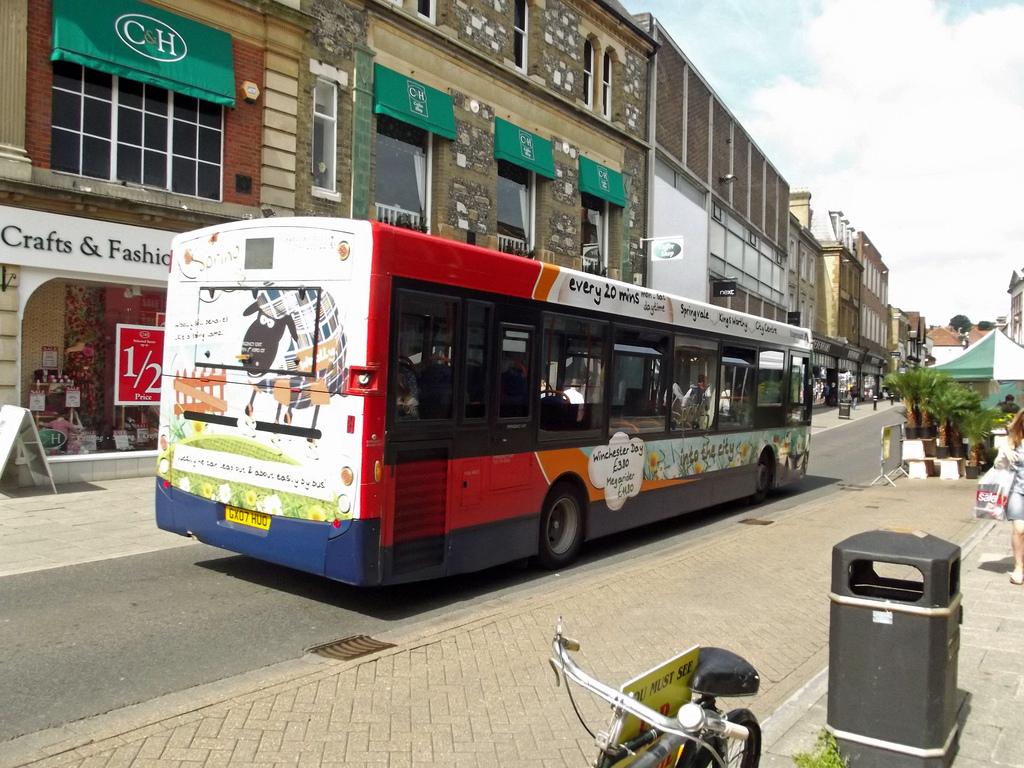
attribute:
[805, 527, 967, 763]
trash can — Grey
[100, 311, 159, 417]
sign — red, white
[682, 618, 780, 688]
seat — black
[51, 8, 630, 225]
greencanopies — green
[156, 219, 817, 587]
bus — Red, blue, white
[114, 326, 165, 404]
poster — red and white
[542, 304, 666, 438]
stripe — orange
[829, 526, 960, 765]
trashcan — black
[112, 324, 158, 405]
redsign — red 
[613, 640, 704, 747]
sign — yellow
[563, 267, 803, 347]
lettering — black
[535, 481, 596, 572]
tire — black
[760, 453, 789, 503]
tire — black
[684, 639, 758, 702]
seat — black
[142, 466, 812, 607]
stripe — blue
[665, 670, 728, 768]
circle —  white